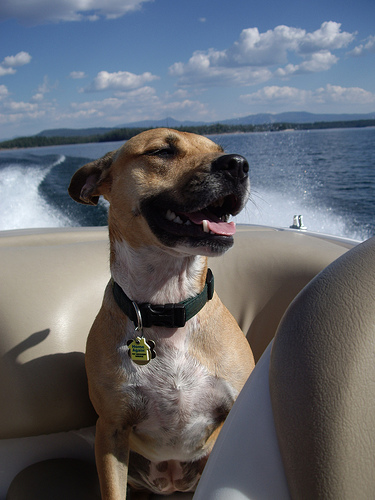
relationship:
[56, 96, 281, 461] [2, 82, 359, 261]
dog on lake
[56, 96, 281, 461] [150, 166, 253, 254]
dog with mouth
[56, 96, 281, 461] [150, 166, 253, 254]
dog has mouth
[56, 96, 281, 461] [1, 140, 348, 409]
dog in boat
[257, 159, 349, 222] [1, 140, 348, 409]
splashing from boat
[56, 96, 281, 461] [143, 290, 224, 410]
dog has spot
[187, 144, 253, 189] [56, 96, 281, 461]
nose of dog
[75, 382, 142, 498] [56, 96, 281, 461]
leg of dog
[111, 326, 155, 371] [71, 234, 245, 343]
tag on collar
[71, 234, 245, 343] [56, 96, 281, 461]
collar on dog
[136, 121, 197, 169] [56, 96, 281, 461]
eye of dog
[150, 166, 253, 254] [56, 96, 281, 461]
mouth of dog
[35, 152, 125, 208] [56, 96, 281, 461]
ear of dog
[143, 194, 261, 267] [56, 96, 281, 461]
tongue of dog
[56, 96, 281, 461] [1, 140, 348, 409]
dog on boat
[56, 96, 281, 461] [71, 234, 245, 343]
dog wears collar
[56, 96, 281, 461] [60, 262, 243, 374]
dog has tags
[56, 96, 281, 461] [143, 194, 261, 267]
dog has tongue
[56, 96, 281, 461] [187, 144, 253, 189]
dog has nose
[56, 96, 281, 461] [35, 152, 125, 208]
dog has ear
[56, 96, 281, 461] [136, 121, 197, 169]
dog has eye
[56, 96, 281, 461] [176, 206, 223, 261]
dog has tooth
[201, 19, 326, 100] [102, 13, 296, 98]
cloud in sky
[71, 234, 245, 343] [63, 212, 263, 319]
collar around neck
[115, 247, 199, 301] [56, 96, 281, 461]
white part of dog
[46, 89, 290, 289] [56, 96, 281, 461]
head of dog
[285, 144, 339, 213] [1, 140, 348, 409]
water next to boat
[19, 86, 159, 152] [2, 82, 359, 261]
tree in distance